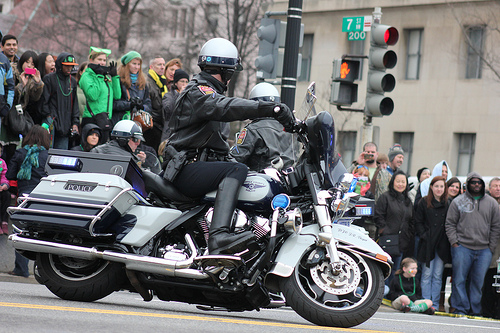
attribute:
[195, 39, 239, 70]
helmet — white, black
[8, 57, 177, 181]
people — watching, dressed, crowd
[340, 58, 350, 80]
hand — bright, red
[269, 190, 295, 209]
light — blue, round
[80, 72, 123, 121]
jacket — green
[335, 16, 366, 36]
sign — green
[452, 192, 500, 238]
hoodie — grey, gray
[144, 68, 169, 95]
scarf — yellow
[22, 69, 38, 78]
phone — pink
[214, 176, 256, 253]
boots — dark, leather, black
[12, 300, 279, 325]
line — yellow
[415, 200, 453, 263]
coat — part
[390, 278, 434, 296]
sweater — part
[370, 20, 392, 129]
traffic light — gray, red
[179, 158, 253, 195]
trouser — black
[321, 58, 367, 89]
light — pedestrian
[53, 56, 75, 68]
cap — green, orange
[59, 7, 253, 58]
trees — foliageless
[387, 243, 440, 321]
girl — sitting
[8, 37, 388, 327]
motorcycle — grey, black, silver